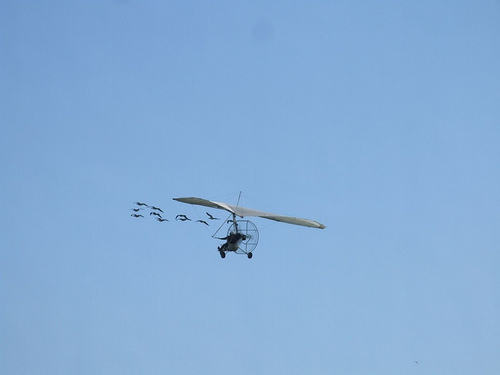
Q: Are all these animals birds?
A: Yes, all the animals are birds.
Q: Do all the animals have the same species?
A: Yes, all the animals are birds.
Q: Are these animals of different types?
A: No, all the animals are birds.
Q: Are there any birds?
A: Yes, there are birds.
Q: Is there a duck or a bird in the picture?
A: Yes, there are birds.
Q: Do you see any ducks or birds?
A: Yes, there are birds.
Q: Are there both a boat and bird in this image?
A: No, there are birds but no boats.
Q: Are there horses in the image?
A: No, there are no horses.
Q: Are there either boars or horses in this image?
A: No, there are no horses or boars.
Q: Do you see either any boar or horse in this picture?
A: No, there are no horses or boars.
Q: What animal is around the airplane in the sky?
A: The birds are around the airplane.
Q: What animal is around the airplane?
A: The birds are around the airplane.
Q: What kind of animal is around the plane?
A: The animals are birds.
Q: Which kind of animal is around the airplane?
A: The animals are birds.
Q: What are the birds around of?
A: The birds are around the airplane.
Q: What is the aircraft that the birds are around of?
A: The aircraft is an airplane.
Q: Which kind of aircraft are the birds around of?
A: The birds are around the plane.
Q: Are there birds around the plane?
A: Yes, there are birds around the plane.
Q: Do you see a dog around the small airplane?
A: No, there are birds around the plane.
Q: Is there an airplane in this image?
A: Yes, there is an airplane.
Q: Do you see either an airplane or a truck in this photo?
A: Yes, there is an airplane.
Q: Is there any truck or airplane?
A: Yes, there is an airplane.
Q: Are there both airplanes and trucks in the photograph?
A: No, there is an airplane but no trucks.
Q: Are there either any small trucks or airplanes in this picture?
A: Yes, there is a small airplane.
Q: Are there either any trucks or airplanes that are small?
A: Yes, the airplane is small.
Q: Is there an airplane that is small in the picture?
A: Yes, there is a small airplane.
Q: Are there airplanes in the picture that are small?
A: Yes, there is a small airplane.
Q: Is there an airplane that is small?
A: Yes, there is an airplane that is small.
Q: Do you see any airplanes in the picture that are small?
A: Yes, there is an airplane that is small.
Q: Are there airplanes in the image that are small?
A: Yes, there is an airplane that is small.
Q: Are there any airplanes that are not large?
A: Yes, there is a small airplane.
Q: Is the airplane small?
A: Yes, the airplane is small.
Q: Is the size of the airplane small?
A: Yes, the airplane is small.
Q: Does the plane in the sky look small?
A: Yes, the plane is small.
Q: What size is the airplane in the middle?
A: The airplane is small.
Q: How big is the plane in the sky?
A: The plane is small.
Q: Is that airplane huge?
A: No, the airplane is small.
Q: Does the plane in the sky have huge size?
A: No, the plane is small.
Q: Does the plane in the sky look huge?
A: No, the plane is small.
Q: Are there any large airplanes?
A: No, there is an airplane but it is small.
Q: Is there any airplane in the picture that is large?
A: No, there is an airplane but it is small.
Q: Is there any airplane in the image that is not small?
A: No, there is an airplane but it is small.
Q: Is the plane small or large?
A: The plane is small.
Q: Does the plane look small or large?
A: The plane is small.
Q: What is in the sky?
A: The plane is in the sky.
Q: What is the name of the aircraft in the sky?
A: The aircraft is an airplane.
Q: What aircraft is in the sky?
A: The aircraft is an airplane.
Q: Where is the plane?
A: The plane is in the sky.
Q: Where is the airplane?
A: The plane is in the sky.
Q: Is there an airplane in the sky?
A: Yes, there is an airplane in the sky.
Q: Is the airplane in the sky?
A: Yes, the airplane is in the sky.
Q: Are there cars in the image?
A: No, there are no cars.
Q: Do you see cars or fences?
A: No, there are no cars or fences.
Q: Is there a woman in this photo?
A: No, there are no women.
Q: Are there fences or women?
A: No, there are no women or fences.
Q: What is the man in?
A: The man is in the airplane.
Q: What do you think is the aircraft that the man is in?
A: The aircraft is an airplane.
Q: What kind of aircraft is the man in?
A: The man is in the plane.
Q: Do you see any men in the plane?
A: Yes, there is a man in the plane.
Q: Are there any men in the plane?
A: Yes, there is a man in the plane.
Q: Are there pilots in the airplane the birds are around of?
A: No, there is a man in the airplane.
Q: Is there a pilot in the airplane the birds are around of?
A: No, there is a man in the airplane.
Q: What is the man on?
A: The man is on the plane.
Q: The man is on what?
A: The man is on the plane.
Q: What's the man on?
A: The man is on the plane.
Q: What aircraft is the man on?
A: The man is on the plane.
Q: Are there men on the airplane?
A: Yes, there is a man on the airplane.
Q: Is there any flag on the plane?
A: No, there is a man on the plane.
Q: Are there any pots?
A: No, there are no pots.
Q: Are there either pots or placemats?
A: No, there are no pots or placemats.